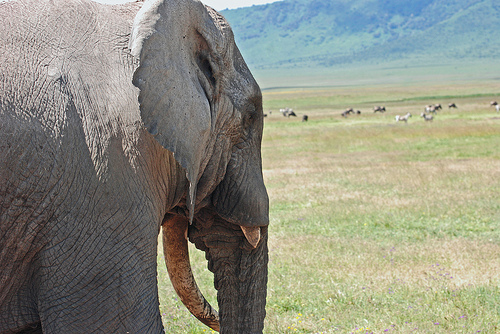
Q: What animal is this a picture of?
A: An elephant.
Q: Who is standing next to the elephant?
A: No one.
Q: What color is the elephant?
A: Grey.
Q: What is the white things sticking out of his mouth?
A: Tusks.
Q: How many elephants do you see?
A: 1.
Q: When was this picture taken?
A: Daytime.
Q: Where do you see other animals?
A: Down in the field.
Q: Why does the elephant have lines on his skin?
A: They are wrinkles.